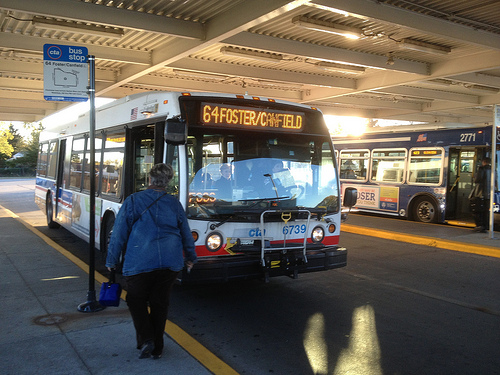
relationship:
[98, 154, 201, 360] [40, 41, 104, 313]
woman at busstop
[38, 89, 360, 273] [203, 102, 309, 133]
bus going to foster/canfield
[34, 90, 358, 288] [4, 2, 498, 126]
bus under roof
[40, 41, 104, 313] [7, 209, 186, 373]
sign on sidewalk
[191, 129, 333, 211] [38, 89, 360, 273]
widshield on bus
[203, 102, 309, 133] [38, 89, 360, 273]
route on bus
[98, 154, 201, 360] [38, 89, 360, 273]
woman by bus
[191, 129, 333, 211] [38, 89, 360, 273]
windshield on bus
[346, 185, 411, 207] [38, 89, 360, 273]
advertisement on bus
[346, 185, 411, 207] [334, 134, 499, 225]
advertisement on bus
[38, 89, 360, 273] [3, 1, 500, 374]
bus at station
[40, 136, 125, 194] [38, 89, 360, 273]
windows on bus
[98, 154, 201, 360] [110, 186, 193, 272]
woman wearing jacket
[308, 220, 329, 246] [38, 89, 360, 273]
headlights on bus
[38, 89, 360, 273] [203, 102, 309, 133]
bus says foster/canfield